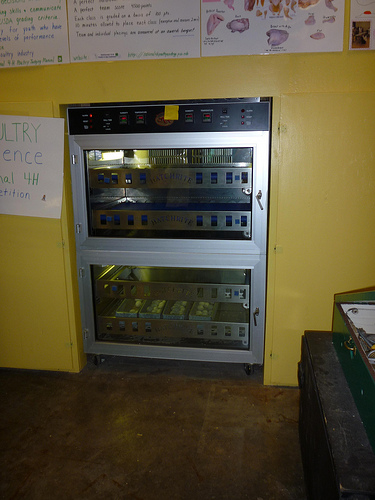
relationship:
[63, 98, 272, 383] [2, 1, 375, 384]
oven in wall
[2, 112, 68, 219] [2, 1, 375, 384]
sign on wall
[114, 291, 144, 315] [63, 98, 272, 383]
bread in oven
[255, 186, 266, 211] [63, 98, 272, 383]
handle on oven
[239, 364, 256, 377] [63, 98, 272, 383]
wheel under oven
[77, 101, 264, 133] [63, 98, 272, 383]
controls are on oven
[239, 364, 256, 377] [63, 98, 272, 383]
wheel on bottom of oven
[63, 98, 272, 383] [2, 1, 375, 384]
oven pushed into wall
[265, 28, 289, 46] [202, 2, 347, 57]
picture on sign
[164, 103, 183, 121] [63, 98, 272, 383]
sticky note on oven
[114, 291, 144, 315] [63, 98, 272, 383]
bread inside oven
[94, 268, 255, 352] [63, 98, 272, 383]
racks are on bottom of oven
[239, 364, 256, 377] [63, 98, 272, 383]
wheel underneath oven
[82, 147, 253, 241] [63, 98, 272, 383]
window on oven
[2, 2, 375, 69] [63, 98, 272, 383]
signs are above oven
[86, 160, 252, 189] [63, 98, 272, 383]
shelf mounted inside oven